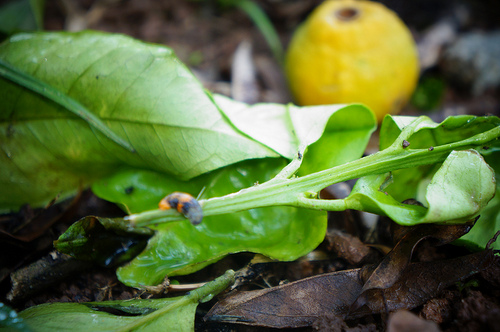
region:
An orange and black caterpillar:
[151, 183, 208, 223]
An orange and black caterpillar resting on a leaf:
[83, 105, 450, 271]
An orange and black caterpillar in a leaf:
[126, 101, 450, 276]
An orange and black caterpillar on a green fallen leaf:
[138, 182, 292, 299]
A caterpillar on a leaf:
[86, 181, 265, 244]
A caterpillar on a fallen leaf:
[95, 144, 407, 298]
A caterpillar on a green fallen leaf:
[117, 148, 395, 295]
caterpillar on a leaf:
[155, 180, 210, 237]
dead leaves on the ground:
[294, 270, 386, 310]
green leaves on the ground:
[163, 85, 321, 237]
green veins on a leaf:
[60, 50, 159, 135]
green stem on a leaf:
[273, 166, 315, 203]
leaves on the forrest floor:
[171, 262, 271, 307]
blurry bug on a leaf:
[153, 177, 213, 237]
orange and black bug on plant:
[153, 174, 203, 236]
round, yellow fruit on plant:
[268, 9, 450, 109]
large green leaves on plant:
[11, 22, 374, 192]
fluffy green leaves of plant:
[0, 3, 492, 293]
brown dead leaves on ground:
[190, 246, 496, 319]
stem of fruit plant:
[221, 5, 421, 152]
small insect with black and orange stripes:
[157, 185, 208, 237]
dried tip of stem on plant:
[0, 233, 65, 308]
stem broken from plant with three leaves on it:
[96, 37, 498, 324]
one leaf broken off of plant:
[3, 264, 248, 329]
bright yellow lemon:
[284, 8, 441, 111]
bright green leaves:
[83, 79, 446, 249]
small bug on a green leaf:
[149, 180, 229, 230]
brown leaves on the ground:
[276, 268, 450, 310]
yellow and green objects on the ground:
[224, 3, 426, 162]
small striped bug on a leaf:
[148, 183, 205, 225]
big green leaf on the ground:
[12, 29, 268, 176]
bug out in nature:
[38, 101, 407, 300]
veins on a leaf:
[38, 35, 154, 105]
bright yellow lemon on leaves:
[280, 1, 422, 125]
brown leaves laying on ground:
[213, 250, 489, 323]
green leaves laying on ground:
[222, 115, 465, 234]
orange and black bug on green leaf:
[157, 182, 205, 229]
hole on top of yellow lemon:
[332, 3, 364, 29]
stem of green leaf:
[187, 261, 236, 306]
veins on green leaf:
[106, 48, 172, 137]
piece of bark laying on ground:
[321, 224, 371, 263]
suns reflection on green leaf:
[202, 95, 332, 149]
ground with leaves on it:
[341, 307, 483, 329]